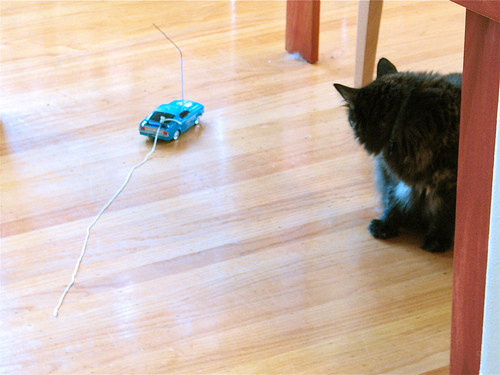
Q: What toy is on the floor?
A: A toy car.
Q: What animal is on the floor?
A: A cat.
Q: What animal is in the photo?
A: Cat.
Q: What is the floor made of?
A: Wood.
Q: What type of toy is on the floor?
A: Car.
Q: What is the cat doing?
A: Sitting down.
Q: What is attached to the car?
A: String.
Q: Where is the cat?
A: Beneath a table.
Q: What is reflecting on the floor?
A: Light.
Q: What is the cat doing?
A: Watching the car.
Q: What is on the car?
A: An antenna.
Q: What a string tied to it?
A: A toy car.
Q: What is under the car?
A: Wooden floor.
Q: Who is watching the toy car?
A: The cat.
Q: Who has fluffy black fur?
A: The cat.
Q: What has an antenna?
A: The toy car.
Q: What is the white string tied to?
A: A toy car.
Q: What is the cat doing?
A: Looking at the toy car.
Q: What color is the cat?
A: Black.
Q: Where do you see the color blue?
A: The toy car.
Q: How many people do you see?
A: 0.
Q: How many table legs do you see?
A: 3.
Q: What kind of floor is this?
A: Hardwood.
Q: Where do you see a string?
A: Tied to the toy car.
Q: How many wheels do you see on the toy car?
A: 2.